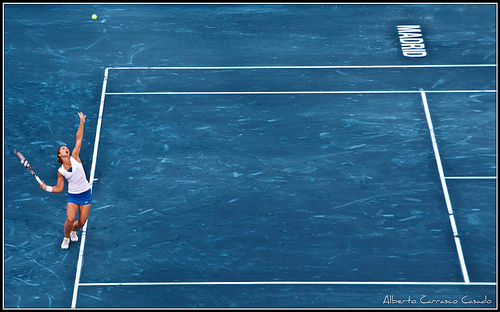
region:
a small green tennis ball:
[87, 13, 101, 20]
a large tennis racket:
[12, 149, 44, 184]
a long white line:
[79, 275, 465, 289]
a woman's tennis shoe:
[58, 236, 71, 248]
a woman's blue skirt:
[62, 192, 95, 206]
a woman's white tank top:
[53, 159, 88, 194]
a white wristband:
[47, 184, 54, 194]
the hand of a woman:
[75, 106, 87, 126]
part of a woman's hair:
[57, 152, 62, 162]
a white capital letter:
[403, 50, 428, 57]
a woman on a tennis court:
[13, 108, 102, 249]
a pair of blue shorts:
[67, 191, 92, 206]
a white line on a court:
[416, 86, 480, 274]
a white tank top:
[58, 152, 92, 195]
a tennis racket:
[11, 142, 41, 186]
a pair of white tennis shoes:
[56, 230, 85, 253]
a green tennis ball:
[88, 11, 98, 26]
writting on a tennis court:
[392, 13, 432, 63]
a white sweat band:
[43, 182, 58, 197]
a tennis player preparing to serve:
[14, 105, 94, 248]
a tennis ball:
[87, 10, 99, 23]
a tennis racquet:
[8, 143, 40, 182]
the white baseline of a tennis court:
[70, 67, 108, 309]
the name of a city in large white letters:
[395, 23, 428, 58]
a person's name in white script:
[382, 293, 493, 306]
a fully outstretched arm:
[73, 108, 85, 154]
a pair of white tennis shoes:
[60, 229, 78, 249]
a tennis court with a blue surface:
[0, 0, 498, 309]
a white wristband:
[44, 180, 54, 192]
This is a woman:
[30, 78, 136, 293]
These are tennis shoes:
[41, 211, 81, 241]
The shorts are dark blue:
[60, 175, 125, 305]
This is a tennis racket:
[0, 110, 25, 200]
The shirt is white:
[60, 130, 107, 215]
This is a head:
[40, 140, 85, 175]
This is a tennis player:
[24, 121, 125, 261]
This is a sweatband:
[37, 188, 46, 196]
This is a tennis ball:
[87, 12, 119, 45]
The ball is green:
[92, 18, 109, 20]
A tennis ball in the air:
[89, 12, 99, 22]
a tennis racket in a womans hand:
[10, 147, 45, 192]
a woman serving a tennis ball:
[12, 108, 100, 253]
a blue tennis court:
[69, 60, 495, 305]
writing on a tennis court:
[393, 21, 430, 58]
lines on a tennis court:
[425, 88, 460, 280]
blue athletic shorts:
[64, 185, 93, 205]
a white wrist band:
[43, 180, 57, 197]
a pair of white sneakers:
[61, 230, 81, 250]